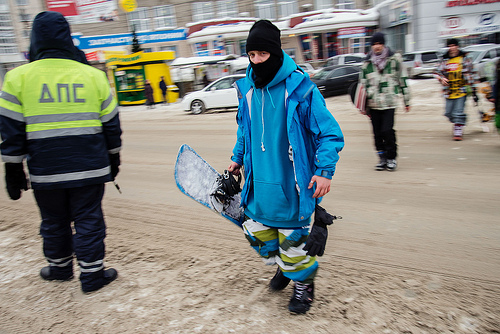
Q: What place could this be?
A: It is a road.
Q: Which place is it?
A: It is a road.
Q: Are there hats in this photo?
A: Yes, there is a hat.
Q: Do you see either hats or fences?
A: Yes, there is a hat.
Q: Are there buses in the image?
A: No, there are no buses.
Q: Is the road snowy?
A: Yes, the road is snowy.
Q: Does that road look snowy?
A: Yes, the road is snowy.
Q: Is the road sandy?
A: No, the road is snowy.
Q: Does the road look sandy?
A: No, the road is snowy.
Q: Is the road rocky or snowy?
A: The road is snowy.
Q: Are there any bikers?
A: No, there are no bikers.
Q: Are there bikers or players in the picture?
A: No, there are no bikers or players.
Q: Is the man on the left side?
A: Yes, the man is on the left of the image.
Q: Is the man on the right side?
A: No, the man is on the left of the image.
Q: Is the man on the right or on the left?
A: The man is on the left of the image.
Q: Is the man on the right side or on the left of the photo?
A: The man is on the left of the image.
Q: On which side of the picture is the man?
A: The man is on the left of the image.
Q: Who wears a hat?
A: The man wears a hat.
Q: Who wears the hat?
A: The man wears a hat.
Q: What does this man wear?
A: The man wears a hat.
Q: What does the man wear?
A: The man wears a hat.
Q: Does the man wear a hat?
A: Yes, the man wears a hat.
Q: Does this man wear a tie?
A: No, the man wears a hat.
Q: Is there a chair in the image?
A: No, there are no chairs.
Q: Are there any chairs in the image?
A: No, there are no chairs.